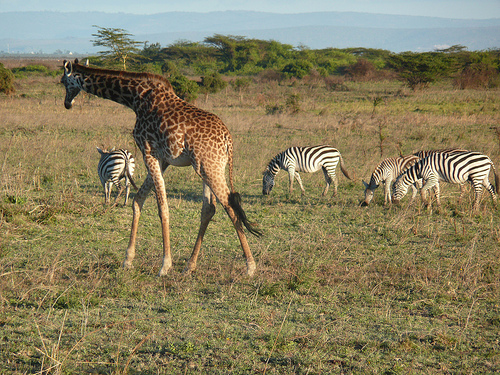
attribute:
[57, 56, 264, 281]
giraffe — lots of spots, very tall, walking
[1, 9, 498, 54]
mountains — in the distance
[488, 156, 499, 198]
long tail — long 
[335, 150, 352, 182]
long tail — long 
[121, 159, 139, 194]
long tail — long 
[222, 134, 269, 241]
long tail — long 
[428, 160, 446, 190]
long tail — long 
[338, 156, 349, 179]
tail — grey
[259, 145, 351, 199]
zebra — black, white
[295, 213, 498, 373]
ground — brown patches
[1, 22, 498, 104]
trees — tall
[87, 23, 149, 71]
tree — green 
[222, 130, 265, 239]
tail — black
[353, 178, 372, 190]
ear — white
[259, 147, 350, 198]
animals — equines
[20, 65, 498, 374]
grass — green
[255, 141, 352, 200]
zebra — black, white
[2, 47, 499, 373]
land — large , open 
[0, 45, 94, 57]
city — on the horizon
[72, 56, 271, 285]
giraffe — spotted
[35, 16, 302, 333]
giraffe — brown, tan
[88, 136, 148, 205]
zebra — back view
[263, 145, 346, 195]
zebra — still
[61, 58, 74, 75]
ear — white